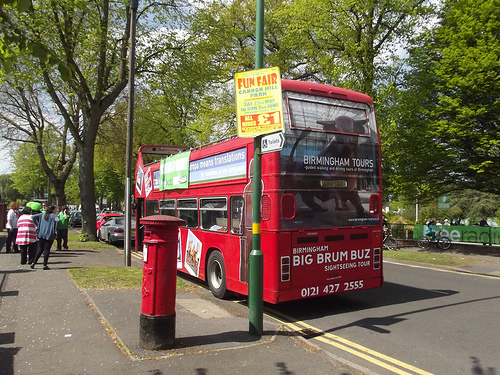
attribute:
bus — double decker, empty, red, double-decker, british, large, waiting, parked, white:
[134, 79, 385, 304]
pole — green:
[247, 0, 269, 338]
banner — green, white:
[156, 151, 192, 193]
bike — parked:
[413, 230, 452, 252]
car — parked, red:
[94, 210, 120, 234]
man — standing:
[30, 202, 59, 270]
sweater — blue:
[31, 211, 60, 240]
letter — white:
[294, 255, 302, 267]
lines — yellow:
[235, 298, 431, 375]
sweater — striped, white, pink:
[15, 214, 37, 245]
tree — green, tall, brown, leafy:
[406, 1, 500, 204]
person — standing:
[15, 208, 41, 267]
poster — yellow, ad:
[235, 65, 286, 140]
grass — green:
[73, 267, 196, 292]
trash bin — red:
[137, 213, 191, 351]